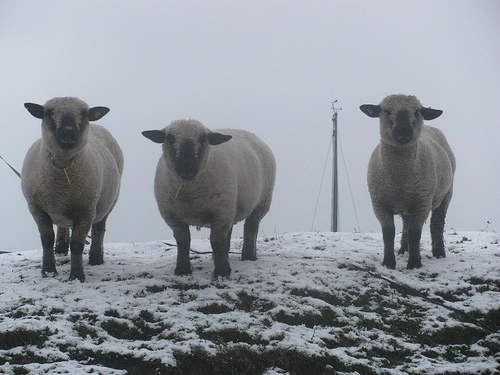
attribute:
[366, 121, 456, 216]
fur — white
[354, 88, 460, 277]
animal — white, fur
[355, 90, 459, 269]
sheep — white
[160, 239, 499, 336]
cable — black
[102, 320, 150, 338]
grass — patch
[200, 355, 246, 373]
grass — patch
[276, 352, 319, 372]
grass — patch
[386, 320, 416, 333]
grass — patch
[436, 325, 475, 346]
grass — patch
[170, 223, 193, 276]
leg — short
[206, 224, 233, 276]
leg — short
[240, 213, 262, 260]
leg — short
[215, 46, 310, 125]
sky — white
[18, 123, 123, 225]
fur — white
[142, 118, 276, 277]
fur — white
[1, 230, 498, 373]
grass — patch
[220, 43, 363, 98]
sky — dark, foggy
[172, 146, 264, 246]
fur — white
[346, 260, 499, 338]
cable — black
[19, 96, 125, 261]
fur — white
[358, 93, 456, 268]
fur — white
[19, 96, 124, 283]
sheep — white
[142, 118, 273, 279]
sheep — white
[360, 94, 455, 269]
sheep — white